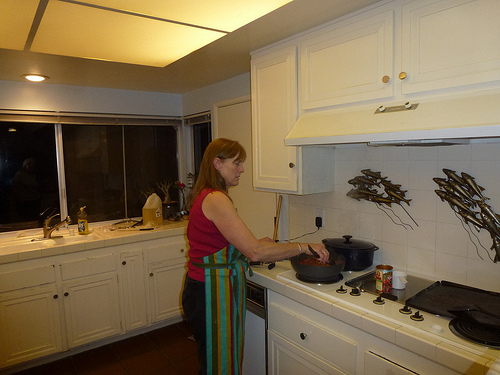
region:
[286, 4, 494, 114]
white kitchen cabinets with gold knobs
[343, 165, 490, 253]
two metal fish sculptures on white tile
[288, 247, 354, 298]
black cast iron skillet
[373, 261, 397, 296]
open can of tomato sauce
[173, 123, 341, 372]
woman cooking dinner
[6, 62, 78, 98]
light fixture in ceiling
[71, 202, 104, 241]
bottle of dish soap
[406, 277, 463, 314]
black metal cookie sheet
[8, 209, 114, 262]
white kitchen sink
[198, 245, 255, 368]
colorful long kitchen apron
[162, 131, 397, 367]
woman cooking in the kitchen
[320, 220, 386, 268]
a blue pot on a back burner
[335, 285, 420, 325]
a bunch of oven dials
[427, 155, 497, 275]
decorative metal fishes on the wall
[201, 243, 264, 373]
woman wearing a colorful striped apron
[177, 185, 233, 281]
woman wearing a red shirt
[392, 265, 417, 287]
a white cup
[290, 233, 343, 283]
woman turning some red sauce in a pan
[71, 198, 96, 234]
yellow dishwashing liquid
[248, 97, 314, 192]
a white cabinet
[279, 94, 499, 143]
a white range vent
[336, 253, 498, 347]
a stove top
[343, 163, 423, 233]
sculpture of a school of fish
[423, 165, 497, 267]
sculpture of a school of fish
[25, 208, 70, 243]
a chrome kitchen faucet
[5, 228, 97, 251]
a kitchen sink basin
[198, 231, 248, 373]
a colorful apron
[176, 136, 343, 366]
a woman cooking on stove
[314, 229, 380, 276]
a black pot on stove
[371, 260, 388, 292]
a jar of tomato sauce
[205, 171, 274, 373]
woman wearing an apron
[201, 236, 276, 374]
apron has long stripes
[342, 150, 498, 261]
fish decorations on the wall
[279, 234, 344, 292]
woman is stirring the pot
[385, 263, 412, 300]
mearuring cup on stove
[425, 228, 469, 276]
white tiles on the wall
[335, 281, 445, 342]
five stove knobs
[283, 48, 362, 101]
kitchen cabinets are white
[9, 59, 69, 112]
light above the sink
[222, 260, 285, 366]
woman standing in front of dishwasher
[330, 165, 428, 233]
fish sculpture on white wall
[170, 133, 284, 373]
woman cooking dinner on stove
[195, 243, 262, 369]
multicolored striped apron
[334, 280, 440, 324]
black and silver dials for stove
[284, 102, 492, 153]
over head fan and exhaust hood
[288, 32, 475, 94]
white wooden kitchen cabinets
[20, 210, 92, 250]
kitchen sink and faucet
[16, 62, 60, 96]
light fixture in the ceiling